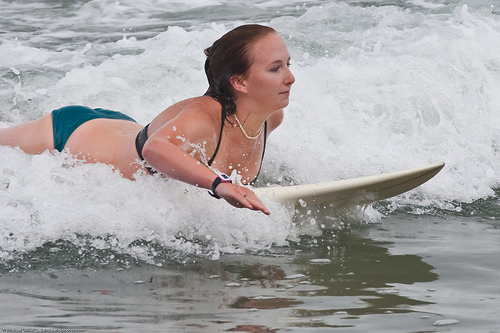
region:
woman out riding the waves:
[40, 18, 457, 258]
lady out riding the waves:
[21, 12, 456, 275]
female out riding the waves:
[59, 2, 456, 282]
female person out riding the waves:
[45, 19, 458, 274]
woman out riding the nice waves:
[55, 6, 452, 293]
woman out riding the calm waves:
[79, 1, 459, 278]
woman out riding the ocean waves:
[42, 0, 461, 262]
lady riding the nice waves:
[35, 21, 466, 264]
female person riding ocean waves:
[38, 15, 449, 295]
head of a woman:
[200, 20, 309, 132]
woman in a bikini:
[2, 24, 295, 216]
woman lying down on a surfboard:
[2, 22, 445, 217]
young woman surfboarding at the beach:
[1, 24, 445, 218]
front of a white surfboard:
[272, 159, 447, 208]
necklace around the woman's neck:
[232, 112, 264, 140]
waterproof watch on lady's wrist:
[205, 171, 233, 200]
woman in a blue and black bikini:
[0, 23, 295, 217]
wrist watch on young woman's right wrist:
[206, 172, 233, 199]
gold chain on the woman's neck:
[232, 112, 262, 139]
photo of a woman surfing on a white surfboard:
[2, 0, 499, 332]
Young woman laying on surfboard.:
[31, 5, 461, 288]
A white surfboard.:
[246, 160, 448, 218]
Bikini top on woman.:
[134, 84, 283, 191]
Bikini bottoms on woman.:
[28, 85, 138, 158]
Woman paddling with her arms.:
[98, 9, 375, 224]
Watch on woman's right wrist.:
[193, 157, 240, 205]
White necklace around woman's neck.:
[218, 106, 301, 143]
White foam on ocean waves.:
[15, 19, 494, 227]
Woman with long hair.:
[183, 11, 305, 158]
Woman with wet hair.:
[189, 12, 309, 144]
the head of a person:
[197, 18, 301, 115]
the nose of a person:
[280, 66, 297, 83]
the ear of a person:
[225, 65, 255, 95]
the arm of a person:
[134, 117, 218, 194]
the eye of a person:
[265, 61, 285, 76]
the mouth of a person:
[271, 87, 292, 98]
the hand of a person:
[210, 173, 275, 217]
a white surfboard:
[243, 150, 445, 219]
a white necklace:
[226, 110, 269, 143]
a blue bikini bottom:
[46, 97, 143, 161]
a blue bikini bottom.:
[47, 94, 146, 156]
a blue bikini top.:
[205, 103, 278, 183]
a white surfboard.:
[240, 158, 452, 239]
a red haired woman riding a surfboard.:
[0, 23, 447, 217]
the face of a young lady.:
[263, 44, 298, 115]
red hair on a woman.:
[198, 18, 276, 115]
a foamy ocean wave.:
[6, 0, 495, 270]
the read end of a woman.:
[0, 86, 131, 162]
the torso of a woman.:
[125, 93, 299, 204]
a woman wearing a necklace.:
[223, 116, 278, 151]